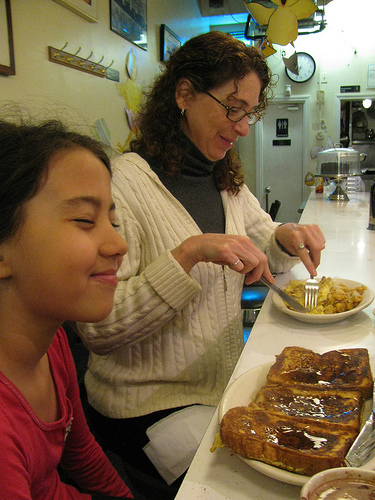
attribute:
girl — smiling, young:
[9, 130, 126, 415]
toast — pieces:
[257, 340, 356, 471]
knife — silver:
[251, 273, 313, 313]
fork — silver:
[303, 264, 323, 304]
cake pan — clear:
[313, 143, 371, 186]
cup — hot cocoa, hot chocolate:
[299, 467, 369, 500]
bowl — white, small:
[262, 290, 369, 331]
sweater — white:
[112, 209, 281, 383]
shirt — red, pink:
[0, 405, 110, 491]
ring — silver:
[289, 238, 310, 251]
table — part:
[192, 202, 372, 498]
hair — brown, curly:
[167, 31, 242, 80]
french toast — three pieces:
[277, 354, 349, 447]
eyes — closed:
[55, 209, 140, 239]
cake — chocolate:
[318, 159, 359, 177]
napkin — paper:
[153, 414, 200, 470]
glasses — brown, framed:
[195, 98, 304, 131]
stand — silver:
[319, 149, 362, 207]